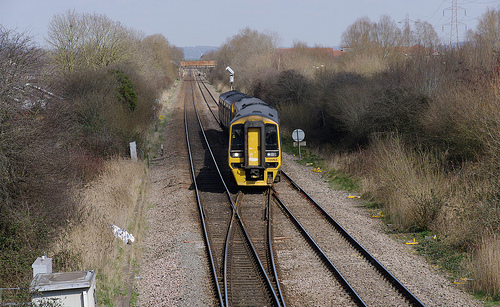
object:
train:
[209, 82, 291, 199]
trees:
[17, 8, 139, 153]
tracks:
[199, 87, 290, 195]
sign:
[287, 126, 310, 159]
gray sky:
[1, 1, 489, 20]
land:
[118, 182, 459, 307]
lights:
[228, 147, 248, 160]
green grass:
[340, 131, 419, 199]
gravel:
[148, 163, 191, 301]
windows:
[229, 125, 248, 151]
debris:
[364, 221, 387, 245]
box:
[28, 254, 102, 306]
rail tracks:
[202, 188, 329, 306]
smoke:
[213, 43, 251, 97]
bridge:
[172, 57, 221, 72]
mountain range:
[163, 41, 222, 59]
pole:
[448, 3, 462, 51]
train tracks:
[180, 54, 318, 307]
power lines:
[424, 2, 443, 24]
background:
[4, 17, 496, 58]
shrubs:
[346, 56, 467, 126]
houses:
[250, 39, 469, 81]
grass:
[373, 120, 454, 224]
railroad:
[173, 63, 430, 307]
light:
[221, 61, 242, 91]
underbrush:
[84, 153, 147, 245]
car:
[224, 103, 284, 188]